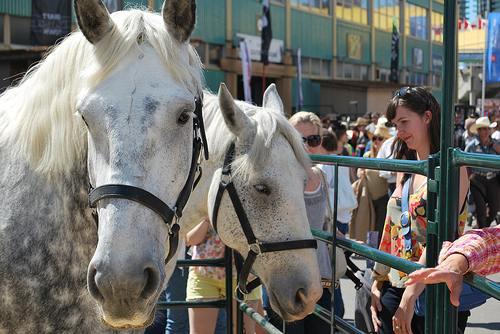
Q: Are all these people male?
A: No, they are both male and female.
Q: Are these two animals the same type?
A: Yes, all the animals are horses.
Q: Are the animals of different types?
A: No, all the animals are horses.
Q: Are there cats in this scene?
A: No, there are no cats.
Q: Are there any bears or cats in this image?
A: No, there are no cats or bears.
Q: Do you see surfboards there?
A: No, there are no surfboards.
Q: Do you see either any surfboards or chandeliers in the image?
A: No, there are no surfboards or chandeliers.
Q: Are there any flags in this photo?
A: Yes, there is a flag.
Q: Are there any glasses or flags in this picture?
A: Yes, there is a flag.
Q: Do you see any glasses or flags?
A: Yes, there is a flag.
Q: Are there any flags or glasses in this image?
A: Yes, there is a flag.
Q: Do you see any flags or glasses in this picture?
A: Yes, there is a flag.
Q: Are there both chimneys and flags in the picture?
A: No, there is a flag but no chimneys.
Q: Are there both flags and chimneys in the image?
A: No, there is a flag but no chimneys.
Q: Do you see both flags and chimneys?
A: No, there is a flag but no chimneys.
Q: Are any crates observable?
A: No, there are no crates.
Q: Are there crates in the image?
A: No, there are no crates.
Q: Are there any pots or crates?
A: No, there are no crates or pots.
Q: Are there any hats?
A: Yes, there is a hat.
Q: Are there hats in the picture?
A: Yes, there is a hat.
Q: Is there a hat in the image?
A: Yes, there is a hat.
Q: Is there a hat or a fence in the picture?
A: Yes, there is a hat.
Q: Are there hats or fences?
A: Yes, there is a hat.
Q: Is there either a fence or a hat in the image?
A: Yes, there is a hat.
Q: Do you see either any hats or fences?
A: Yes, there is a hat.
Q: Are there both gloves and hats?
A: No, there is a hat but no gloves.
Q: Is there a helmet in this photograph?
A: No, there are no helmets.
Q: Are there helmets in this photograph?
A: No, there are no helmets.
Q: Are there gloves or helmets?
A: No, there are no helmets or gloves.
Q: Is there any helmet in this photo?
A: No, there are no helmets.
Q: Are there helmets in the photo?
A: No, there are no helmets.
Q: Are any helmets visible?
A: No, there are no helmets.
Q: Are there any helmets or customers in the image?
A: No, there are no helmets or customers.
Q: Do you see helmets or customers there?
A: No, there are no helmets or customers.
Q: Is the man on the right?
A: Yes, the man is on the right of the image.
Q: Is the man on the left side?
A: No, the man is on the right of the image.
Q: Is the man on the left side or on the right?
A: The man is on the right of the image.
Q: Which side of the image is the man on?
A: The man is on the right of the image.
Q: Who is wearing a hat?
A: The man is wearing a hat.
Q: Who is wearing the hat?
A: The man is wearing a hat.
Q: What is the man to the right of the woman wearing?
A: The man is wearing a hat.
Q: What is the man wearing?
A: The man is wearing a hat.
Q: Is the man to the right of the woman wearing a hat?
A: Yes, the man is wearing a hat.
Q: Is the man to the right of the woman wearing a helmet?
A: No, the man is wearing a hat.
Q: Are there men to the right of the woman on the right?
A: Yes, there is a man to the right of the woman.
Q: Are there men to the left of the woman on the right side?
A: No, the man is to the right of the woman.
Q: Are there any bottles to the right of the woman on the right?
A: No, there is a man to the right of the woman.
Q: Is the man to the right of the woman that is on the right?
A: Yes, the man is to the right of the woman.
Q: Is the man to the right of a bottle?
A: No, the man is to the right of the woman.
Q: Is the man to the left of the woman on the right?
A: No, the man is to the right of the woman.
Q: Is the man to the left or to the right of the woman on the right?
A: The man is to the right of the woman.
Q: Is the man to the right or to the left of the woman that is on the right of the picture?
A: The man is to the right of the woman.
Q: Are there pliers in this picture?
A: No, there are no pliers.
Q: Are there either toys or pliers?
A: No, there are no pliers or toys.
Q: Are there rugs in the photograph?
A: No, there are no rugs.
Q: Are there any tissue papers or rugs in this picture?
A: No, there are no rugs or tissue papers.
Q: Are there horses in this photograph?
A: Yes, there is a horse.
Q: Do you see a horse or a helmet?
A: Yes, there is a horse.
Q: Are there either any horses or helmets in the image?
A: Yes, there is a horse.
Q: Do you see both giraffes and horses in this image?
A: No, there is a horse but no giraffes.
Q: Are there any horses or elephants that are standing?
A: Yes, the horse is standing.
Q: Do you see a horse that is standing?
A: Yes, there is a horse that is standing.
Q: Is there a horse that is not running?
A: Yes, there is a horse that is standing.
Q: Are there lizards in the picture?
A: No, there are no lizards.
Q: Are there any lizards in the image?
A: No, there are no lizards.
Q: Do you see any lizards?
A: No, there are no lizards.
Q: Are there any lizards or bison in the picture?
A: No, there are no lizards or bison.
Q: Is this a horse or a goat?
A: This is a horse.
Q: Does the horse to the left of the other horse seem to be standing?
A: Yes, the horse is standing.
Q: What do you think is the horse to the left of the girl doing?
A: The horse is standing.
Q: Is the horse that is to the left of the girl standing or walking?
A: The horse is standing.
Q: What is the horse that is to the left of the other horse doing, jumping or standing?
A: The horse is standing.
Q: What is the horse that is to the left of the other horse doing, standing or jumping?
A: The horse is standing.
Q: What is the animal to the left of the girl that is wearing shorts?
A: The animal is a horse.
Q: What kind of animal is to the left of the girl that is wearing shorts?
A: The animal is a horse.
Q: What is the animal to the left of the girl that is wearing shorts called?
A: The animal is a horse.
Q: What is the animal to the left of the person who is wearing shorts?
A: The animal is a horse.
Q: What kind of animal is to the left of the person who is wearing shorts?
A: The animal is a horse.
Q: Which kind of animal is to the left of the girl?
A: The animal is a horse.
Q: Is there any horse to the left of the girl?
A: Yes, there is a horse to the left of the girl.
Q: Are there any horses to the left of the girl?
A: Yes, there is a horse to the left of the girl.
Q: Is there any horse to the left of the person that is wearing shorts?
A: Yes, there is a horse to the left of the girl.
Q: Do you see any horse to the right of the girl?
A: No, the horse is to the left of the girl.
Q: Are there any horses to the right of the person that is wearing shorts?
A: No, the horse is to the left of the girl.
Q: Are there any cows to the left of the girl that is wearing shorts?
A: No, there is a horse to the left of the girl.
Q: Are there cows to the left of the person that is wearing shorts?
A: No, there is a horse to the left of the girl.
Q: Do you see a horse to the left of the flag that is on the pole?
A: Yes, there is a horse to the left of the flag.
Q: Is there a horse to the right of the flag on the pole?
A: No, the horse is to the left of the flag.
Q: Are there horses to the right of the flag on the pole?
A: No, the horse is to the left of the flag.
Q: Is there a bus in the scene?
A: No, there are no buses.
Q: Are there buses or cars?
A: No, there are no buses or cars.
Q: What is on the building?
A: The sign is on the building.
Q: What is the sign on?
A: The sign is on the building.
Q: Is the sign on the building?
A: Yes, the sign is on the building.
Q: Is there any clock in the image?
A: No, there are no clocks.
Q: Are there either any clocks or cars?
A: No, there are no clocks or cars.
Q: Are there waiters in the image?
A: No, there are no waiters.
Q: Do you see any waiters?
A: No, there are no waiters.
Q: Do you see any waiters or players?
A: No, there are no waiters or players.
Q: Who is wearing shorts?
A: The girl is wearing shorts.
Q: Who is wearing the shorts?
A: The girl is wearing shorts.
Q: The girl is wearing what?
A: The girl is wearing shorts.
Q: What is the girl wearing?
A: The girl is wearing shorts.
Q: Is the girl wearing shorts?
A: Yes, the girl is wearing shorts.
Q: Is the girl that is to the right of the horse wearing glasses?
A: No, the girl is wearing shorts.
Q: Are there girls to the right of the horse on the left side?
A: Yes, there is a girl to the right of the horse.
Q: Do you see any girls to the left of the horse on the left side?
A: No, the girl is to the right of the horse.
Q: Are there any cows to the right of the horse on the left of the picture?
A: No, there is a girl to the right of the horse.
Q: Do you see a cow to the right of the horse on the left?
A: No, there is a girl to the right of the horse.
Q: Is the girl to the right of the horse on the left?
A: Yes, the girl is to the right of the horse.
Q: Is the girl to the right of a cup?
A: No, the girl is to the right of the horse.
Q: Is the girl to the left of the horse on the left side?
A: No, the girl is to the right of the horse.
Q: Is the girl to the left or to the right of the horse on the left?
A: The girl is to the right of the horse.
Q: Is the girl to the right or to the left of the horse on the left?
A: The girl is to the right of the horse.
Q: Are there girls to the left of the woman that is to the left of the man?
A: Yes, there is a girl to the left of the woman.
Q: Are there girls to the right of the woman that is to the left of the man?
A: No, the girl is to the left of the woman.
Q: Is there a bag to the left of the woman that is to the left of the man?
A: No, there is a girl to the left of the woman.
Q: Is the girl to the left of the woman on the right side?
A: Yes, the girl is to the left of the woman.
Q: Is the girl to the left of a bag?
A: No, the girl is to the left of the woman.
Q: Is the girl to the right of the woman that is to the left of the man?
A: No, the girl is to the left of the woman.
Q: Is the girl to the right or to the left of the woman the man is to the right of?
A: The girl is to the left of the woman.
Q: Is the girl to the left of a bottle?
A: No, the girl is to the left of the woman.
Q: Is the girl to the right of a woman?
A: No, the girl is to the left of a woman.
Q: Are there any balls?
A: No, there are no balls.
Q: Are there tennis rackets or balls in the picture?
A: No, there are no balls or tennis rackets.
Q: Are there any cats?
A: No, there are no cats.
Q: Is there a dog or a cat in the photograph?
A: No, there are no cats or dogs.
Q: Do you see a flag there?
A: Yes, there is a flag.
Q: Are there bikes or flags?
A: Yes, there is a flag.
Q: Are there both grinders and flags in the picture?
A: No, there is a flag but no grinders.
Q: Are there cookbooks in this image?
A: No, there are no cookbooks.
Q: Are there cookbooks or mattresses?
A: No, there are no cookbooks or mattresses.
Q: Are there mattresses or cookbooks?
A: No, there are no cookbooks or mattresses.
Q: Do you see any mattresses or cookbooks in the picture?
A: No, there are no cookbooks or mattresses.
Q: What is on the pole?
A: The flag is on the pole.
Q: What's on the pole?
A: The flag is on the pole.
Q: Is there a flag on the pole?
A: Yes, there is a flag on the pole.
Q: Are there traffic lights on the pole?
A: No, there is a flag on the pole.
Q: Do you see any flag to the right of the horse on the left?
A: Yes, there is a flag to the right of the horse.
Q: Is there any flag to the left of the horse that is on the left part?
A: No, the flag is to the right of the horse.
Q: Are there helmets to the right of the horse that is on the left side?
A: No, there is a flag to the right of the horse.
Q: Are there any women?
A: Yes, there is a woman.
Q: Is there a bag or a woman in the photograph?
A: Yes, there is a woman.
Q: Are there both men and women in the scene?
A: Yes, there are both a woman and a man.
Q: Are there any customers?
A: No, there are no customers.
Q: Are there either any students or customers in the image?
A: No, there are no customers or students.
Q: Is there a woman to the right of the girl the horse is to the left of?
A: Yes, there is a woman to the right of the girl.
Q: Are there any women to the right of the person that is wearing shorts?
A: Yes, there is a woman to the right of the girl.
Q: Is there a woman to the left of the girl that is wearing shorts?
A: No, the woman is to the right of the girl.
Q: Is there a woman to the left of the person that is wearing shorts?
A: No, the woman is to the right of the girl.